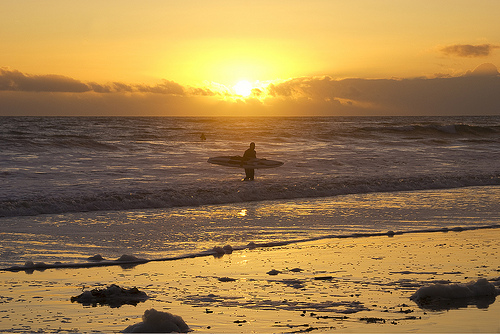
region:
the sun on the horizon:
[190, 44, 306, 121]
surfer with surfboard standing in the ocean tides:
[211, 141, 285, 183]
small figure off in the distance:
[198, 129, 208, 141]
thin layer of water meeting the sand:
[10, 202, 497, 232]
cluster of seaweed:
[68, 283, 149, 305]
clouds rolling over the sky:
[273, 70, 486, 110]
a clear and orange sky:
[3, 3, 432, 72]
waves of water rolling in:
[311, 120, 493, 145]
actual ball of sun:
[233, 78, 254, 98]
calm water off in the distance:
[3, 115, 498, 121]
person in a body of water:
[217, 120, 284, 196]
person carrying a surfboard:
[206, 136, 277, 178]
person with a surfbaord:
[221, 132, 282, 190]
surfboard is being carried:
[204, 151, 301, 173]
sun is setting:
[219, 74, 260, 105]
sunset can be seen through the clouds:
[220, 73, 302, 110]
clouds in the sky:
[307, 69, 473, 107]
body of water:
[53, 135, 105, 170]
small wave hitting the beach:
[323, 151, 413, 213]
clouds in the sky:
[28, 70, 110, 96]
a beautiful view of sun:
[187, 50, 339, 133]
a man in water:
[178, 136, 325, 200]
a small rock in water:
[36, 250, 168, 322]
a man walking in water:
[208, 109, 314, 225]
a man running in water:
[211, 134, 315, 222]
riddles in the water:
[93, 167, 490, 257]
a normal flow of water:
[18, 179, 498, 256]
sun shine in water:
[232, 199, 262, 226]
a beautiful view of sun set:
[38, 15, 489, 155]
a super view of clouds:
[13, 63, 498, 119]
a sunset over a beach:
[20, 30, 477, 250]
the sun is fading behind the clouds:
[22, 42, 467, 119]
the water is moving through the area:
[22, 102, 491, 221]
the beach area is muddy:
[42, 218, 499, 331]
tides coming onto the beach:
[30, 213, 449, 285]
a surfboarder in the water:
[199, 134, 302, 201]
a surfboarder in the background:
[189, 124, 215, 141]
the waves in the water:
[10, 108, 495, 185]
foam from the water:
[12, 231, 484, 281]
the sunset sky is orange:
[22, 11, 482, 115]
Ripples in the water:
[5, 183, 55, 217]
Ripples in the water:
[62, 175, 99, 215]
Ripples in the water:
[102, 167, 159, 209]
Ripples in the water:
[164, 162, 213, 212]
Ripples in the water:
[207, 167, 285, 202]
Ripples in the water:
[278, 155, 336, 202]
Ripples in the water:
[327, 162, 386, 196]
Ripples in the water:
[374, 153, 431, 195]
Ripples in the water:
[418, 160, 468, 178]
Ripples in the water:
[299, 123, 364, 164]